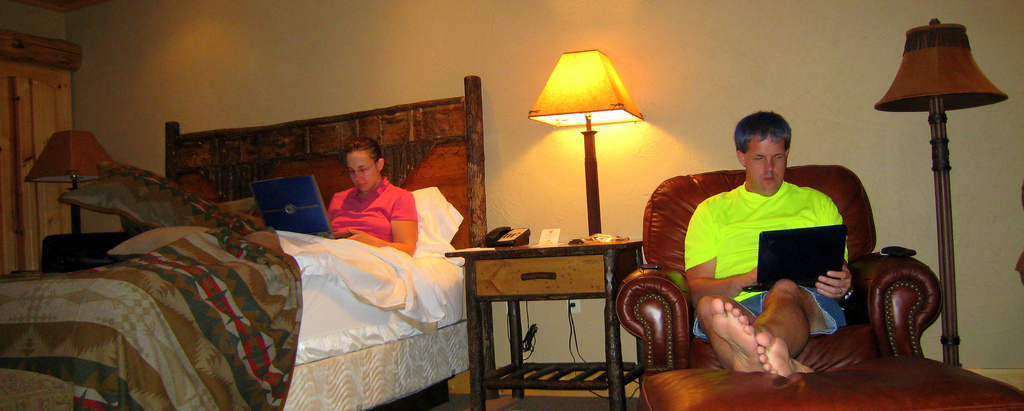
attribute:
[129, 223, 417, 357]
blanket — pulled back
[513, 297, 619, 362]
cord — plugged in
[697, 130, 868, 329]
man — sitting down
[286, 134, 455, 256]
man — sitting down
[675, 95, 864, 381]
man — sitting down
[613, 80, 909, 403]
man — sitting down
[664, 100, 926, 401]
man — holding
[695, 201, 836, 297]
laptop — black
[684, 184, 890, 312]
shirt — yellow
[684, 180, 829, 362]
shirt — yellow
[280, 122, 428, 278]
woman — sitting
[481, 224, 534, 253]
telephone — black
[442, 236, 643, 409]
table — normal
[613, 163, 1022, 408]
chair — large, brown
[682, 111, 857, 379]
person — sitting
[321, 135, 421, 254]
person — sitting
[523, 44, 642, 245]
table lamp — tall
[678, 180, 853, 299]
shirt — green, short sleeved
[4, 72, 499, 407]
bed — large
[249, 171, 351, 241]
laptop — blue, gray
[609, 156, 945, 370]
chair — leather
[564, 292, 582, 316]
wall outlet — white